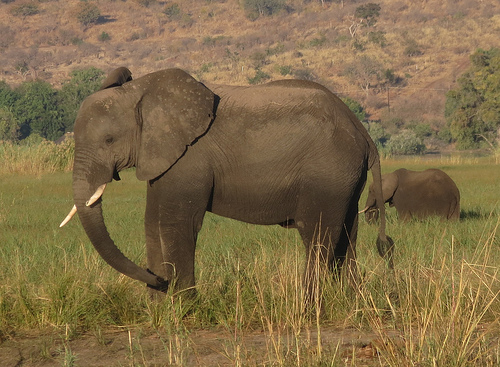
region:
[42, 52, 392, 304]
The elephant is grey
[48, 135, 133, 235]
The elephant has white tusks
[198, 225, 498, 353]
The grass is tall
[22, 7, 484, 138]
The hillside is brown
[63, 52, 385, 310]
The elephant is standing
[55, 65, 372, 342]
The elephant is on top of the grass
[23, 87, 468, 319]
A large grassy field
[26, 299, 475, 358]
Dirt in front of the elephant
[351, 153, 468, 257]
The elephant is eating grass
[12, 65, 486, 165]
Trees at the base of the hill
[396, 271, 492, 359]
tall yellow thin grass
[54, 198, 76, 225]
slightly worn cream colored ivory tusk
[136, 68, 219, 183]
large floppy elephant ear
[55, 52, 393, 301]
large African elephant snoozing on feet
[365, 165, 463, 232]
small African elephant in high grass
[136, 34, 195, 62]
dead dried out brush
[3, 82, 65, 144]
vibrant wild trees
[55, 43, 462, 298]
two elephants in their natural habitat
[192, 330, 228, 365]
small patch of dirt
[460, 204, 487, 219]
shadow cast upon grass by small elephant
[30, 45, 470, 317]
elephants on grassy plain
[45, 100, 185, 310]
trunk curled toward front legs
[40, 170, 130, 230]
tusks slanted away from mouth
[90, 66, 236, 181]
lighter spots on elephant's ear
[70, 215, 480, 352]
tall tan grasses in front of green grass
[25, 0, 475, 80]
dry and brown slope in back of elephant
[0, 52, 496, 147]
green trees at bottom of slope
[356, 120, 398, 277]
tail in front of elephant in back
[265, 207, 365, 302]
grass covering rear legs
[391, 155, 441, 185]
curve into elephant's back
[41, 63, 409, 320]
an elephant standing on the grass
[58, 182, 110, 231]
the jaws of an elephant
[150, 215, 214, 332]
front two legs of elephant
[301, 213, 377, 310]
back two legs of elephant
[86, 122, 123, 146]
eye of an elephant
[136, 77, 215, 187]
ear of an elephant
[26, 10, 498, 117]
desert on back side of elephant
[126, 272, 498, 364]
green grass present on the ground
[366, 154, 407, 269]
the elephant tail on the back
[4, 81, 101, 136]
trees on backside of elephant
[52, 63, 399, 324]
elephant standing in grassy field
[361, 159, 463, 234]
elephant standing in grassy field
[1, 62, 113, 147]
dark green trees at the bottom of a hill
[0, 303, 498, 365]
patch of brown dirt in the middle of a large field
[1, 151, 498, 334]
large open field of high green grass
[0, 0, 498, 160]
hill covered in shrubs and bushes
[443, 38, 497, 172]
large tree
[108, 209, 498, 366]
high row of dry grass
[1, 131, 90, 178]
thick patch of light green bushes near the edge of a field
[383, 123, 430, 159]
large light green bush